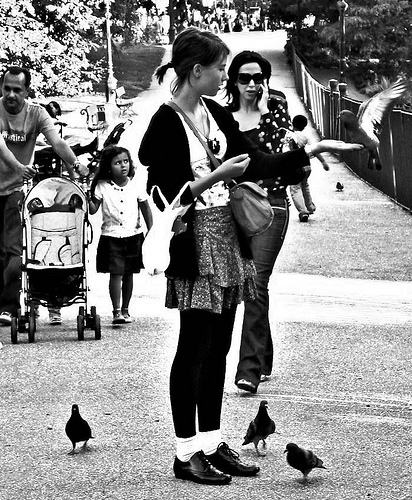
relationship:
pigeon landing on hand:
[325, 73, 406, 170] [313, 132, 364, 154]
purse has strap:
[175, 103, 283, 237] [168, 92, 225, 160]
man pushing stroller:
[2, 62, 92, 184] [6, 168, 107, 346]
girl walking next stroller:
[89, 146, 154, 324] [6, 168, 107, 346]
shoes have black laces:
[172, 442, 266, 490] [198, 443, 241, 468]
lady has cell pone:
[227, 41, 314, 386] [253, 78, 272, 100]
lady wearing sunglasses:
[227, 41, 314, 386] [234, 69, 267, 87]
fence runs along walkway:
[287, 44, 411, 207] [124, 23, 366, 266]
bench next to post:
[77, 103, 113, 140] [102, 1, 119, 120]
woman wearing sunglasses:
[227, 41, 314, 386] [234, 69, 267, 87]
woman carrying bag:
[128, 19, 270, 491] [132, 177, 200, 276]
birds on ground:
[64, 403, 96, 456] [12, 342, 400, 491]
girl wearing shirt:
[89, 146, 154, 324] [90, 178, 151, 239]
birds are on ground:
[55, 391, 330, 489] [12, 342, 400, 491]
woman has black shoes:
[128, 19, 270, 491] [172, 442, 266, 490]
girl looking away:
[89, 146, 154, 324] [108, 152, 137, 169]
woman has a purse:
[128, 19, 270, 491] [175, 103, 283, 237]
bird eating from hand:
[325, 73, 406, 170] [313, 132, 364, 154]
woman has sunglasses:
[227, 41, 314, 386] [234, 69, 267, 87]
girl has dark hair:
[89, 146, 154, 324] [86, 141, 141, 199]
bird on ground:
[276, 432, 330, 487] [12, 342, 400, 491]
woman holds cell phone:
[227, 41, 314, 386] [253, 78, 272, 100]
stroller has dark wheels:
[6, 168, 107, 346] [6, 301, 104, 345]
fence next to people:
[287, 44, 411, 207] [294, 105, 322, 220]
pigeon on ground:
[240, 395, 280, 459] [12, 342, 400, 491]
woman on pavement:
[128, 19, 270, 491] [12, 342, 400, 491]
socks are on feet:
[172, 433, 224, 461] [172, 442, 266, 490]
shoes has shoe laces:
[172, 442, 266, 490] [198, 443, 241, 468]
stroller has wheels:
[6, 168, 107, 346] [6, 301, 104, 345]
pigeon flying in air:
[325, 73, 406, 170] [281, 16, 411, 171]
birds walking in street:
[64, 403, 96, 456] [12, 342, 400, 491]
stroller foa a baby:
[6, 168, 107, 346] [24, 203, 78, 264]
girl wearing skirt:
[89, 145, 153, 324] [93, 232, 148, 280]